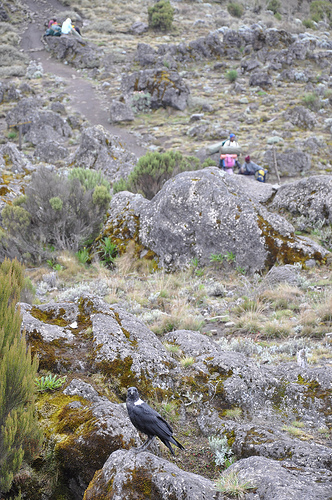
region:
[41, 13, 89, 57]
two hikers sitting on a rock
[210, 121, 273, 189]
two hikers sitting on a rock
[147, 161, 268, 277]
large boulder on a hiking trail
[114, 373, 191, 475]
black bird perched on a rock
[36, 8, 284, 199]
four hikers on a rocky trail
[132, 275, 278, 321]
scrub brush on rocky land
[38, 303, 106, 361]
green moss growing onthe rocks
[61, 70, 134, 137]
smooth path between rocks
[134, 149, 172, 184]
green bushes growing next to rocks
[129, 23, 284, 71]
rock wall on a rock path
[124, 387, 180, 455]
black and white bird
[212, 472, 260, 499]
green grass growing on rock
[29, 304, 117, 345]
green moss on side of rock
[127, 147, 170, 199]
tree with green leaves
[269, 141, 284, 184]
brown stick leaning on rock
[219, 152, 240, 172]
person with pink backpack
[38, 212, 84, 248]
dead grey bush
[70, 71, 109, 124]
dirt path on mountainside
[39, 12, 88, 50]
people sitting on large boulder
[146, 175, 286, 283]
large grey boulder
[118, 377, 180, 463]
The bird is black.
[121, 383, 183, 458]
Bird standing on rock.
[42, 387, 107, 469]
Moss growing on rocks.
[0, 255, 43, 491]
The bush is green.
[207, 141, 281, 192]
People climbing on rocks.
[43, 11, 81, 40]
People sitting on rocks.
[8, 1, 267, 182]
The trail is grey.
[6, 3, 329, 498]
The rocks are grey.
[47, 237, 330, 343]
the grass is brown.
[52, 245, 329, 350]
the grass is dry.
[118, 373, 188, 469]
A dark colord bird.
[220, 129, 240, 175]
A person out of focus.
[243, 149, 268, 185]
A person out of focus.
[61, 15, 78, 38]
A person out of focus.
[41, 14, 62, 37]
A person out of focus.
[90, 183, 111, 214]
A green bush.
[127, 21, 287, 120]
A group of rocks.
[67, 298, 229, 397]
A group of rocks.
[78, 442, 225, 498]
The rock the bird is standing on.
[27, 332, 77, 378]
Some moss growing on the rock.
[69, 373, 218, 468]
the bird is black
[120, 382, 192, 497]
the bird is black